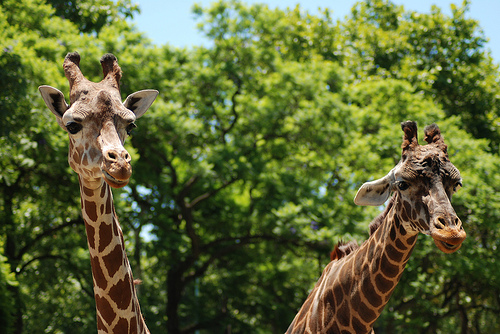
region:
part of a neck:
[321, 239, 384, 324]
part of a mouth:
[433, 215, 467, 272]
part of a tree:
[173, 270, 198, 302]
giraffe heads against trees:
[12, 25, 469, 322]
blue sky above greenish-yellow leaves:
[120, 0, 495, 120]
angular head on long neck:
[35, 45, 155, 325]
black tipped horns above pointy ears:
[35, 45, 155, 120]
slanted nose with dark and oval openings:
[96, 110, 131, 161]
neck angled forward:
[265, 105, 466, 326]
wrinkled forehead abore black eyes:
[390, 140, 460, 190]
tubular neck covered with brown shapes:
[75, 185, 145, 330]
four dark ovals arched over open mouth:
[430, 211, 465, 251]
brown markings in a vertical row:
[342, 240, 408, 326]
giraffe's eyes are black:
[43, 108, 155, 161]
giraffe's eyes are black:
[376, 169, 472, 204]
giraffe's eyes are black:
[54, 101, 168, 140]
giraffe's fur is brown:
[66, 183, 155, 323]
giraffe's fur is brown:
[271, 168, 421, 315]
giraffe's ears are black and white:
[25, 73, 175, 141]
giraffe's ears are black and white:
[345, 150, 402, 217]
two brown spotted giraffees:
[8, 28, 453, 330]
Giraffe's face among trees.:
[350, 118, 467, 255]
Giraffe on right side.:
[292, 123, 471, 330]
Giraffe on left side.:
[32, 49, 163, 331]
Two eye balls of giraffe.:
[393, 179, 462, 191]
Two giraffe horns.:
[62, 49, 122, 83]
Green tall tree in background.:
[0, 18, 490, 330]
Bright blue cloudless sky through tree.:
[134, 8, 489, 44]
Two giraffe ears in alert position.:
[35, 84, 159, 123]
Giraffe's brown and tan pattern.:
[328, 263, 375, 332]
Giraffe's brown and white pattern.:
[95, 234, 123, 330]